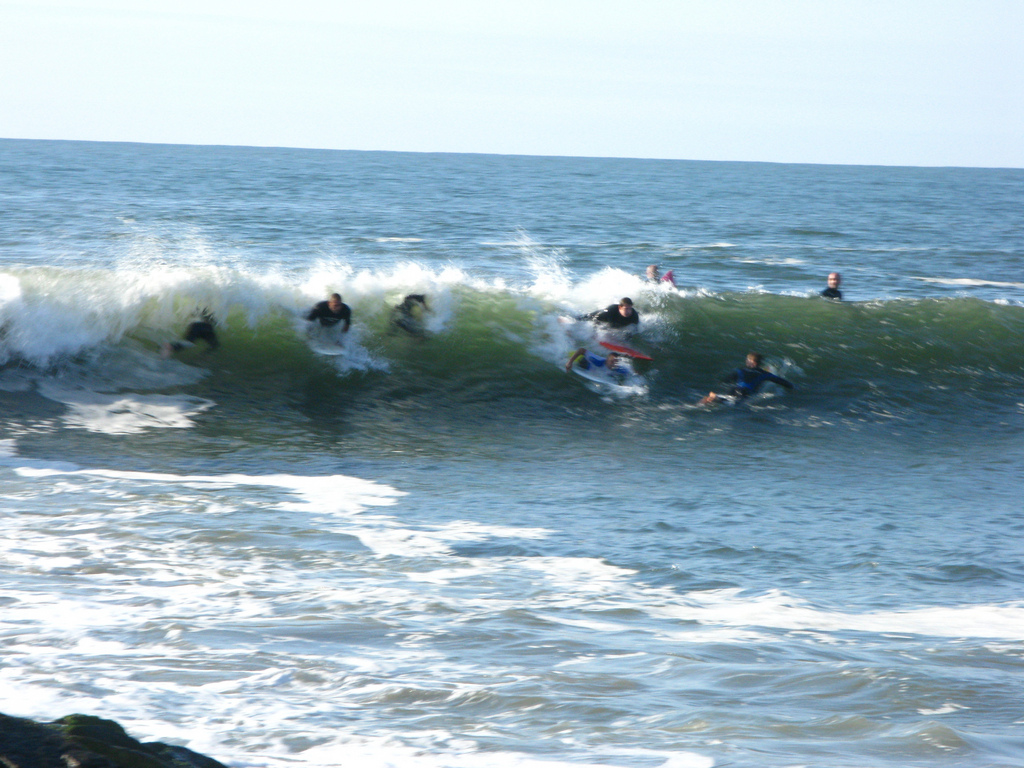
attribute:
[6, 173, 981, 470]
waves — White 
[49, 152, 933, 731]
water — Green 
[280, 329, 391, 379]
surfboard — white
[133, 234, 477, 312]
splash — white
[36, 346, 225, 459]
foam — white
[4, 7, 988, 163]
sky — very clear, white, blue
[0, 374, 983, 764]
waves — white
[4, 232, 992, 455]
waves — small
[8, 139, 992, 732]
ocean — green, blue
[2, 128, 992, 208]
horizon — white, gray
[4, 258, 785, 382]
wave — short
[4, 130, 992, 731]
water — green, white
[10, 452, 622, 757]
breakers — small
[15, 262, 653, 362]
sea foam — white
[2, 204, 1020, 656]
ocean waves — white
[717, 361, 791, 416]
wetsuit — black